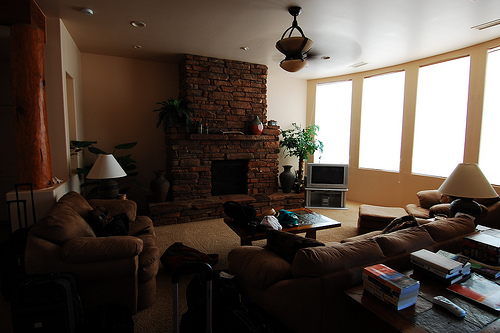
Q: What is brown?
A: Fireplace.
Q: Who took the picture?
A: Man.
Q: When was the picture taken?
A: Daytime.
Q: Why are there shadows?
A: Sunlight.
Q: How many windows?
A: Four.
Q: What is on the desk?
A: Books.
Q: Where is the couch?
A: Left of the fireplace.